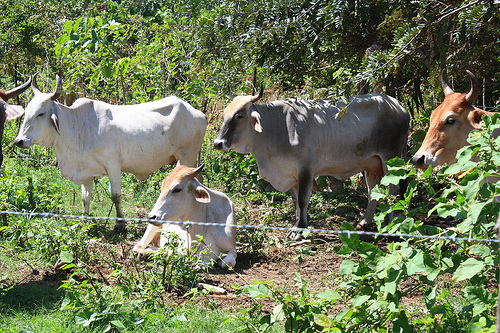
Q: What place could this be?
A: It is a field.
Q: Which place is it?
A: It is a field.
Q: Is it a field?
A: Yes, it is a field.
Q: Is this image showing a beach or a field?
A: It is showing a field.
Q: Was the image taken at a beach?
A: No, the picture was taken in a field.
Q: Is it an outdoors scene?
A: Yes, it is outdoors.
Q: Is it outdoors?
A: Yes, it is outdoors.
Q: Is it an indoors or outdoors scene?
A: It is outdoors.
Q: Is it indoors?
A: No, it is outdoors.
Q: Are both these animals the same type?
A: Yes, all the animals are bulls.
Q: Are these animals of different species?
A: No, all the animals are bulls.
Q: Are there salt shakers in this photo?
A: No, there are no salt shakers.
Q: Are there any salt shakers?
A: No, there are no salt shakers.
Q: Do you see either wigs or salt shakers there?
A: No, there are no salt shakers or wigs.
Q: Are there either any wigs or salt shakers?
A: No, there are no salt shakers or wigs.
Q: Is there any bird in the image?
A: No, there are no birds.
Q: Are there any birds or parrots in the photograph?
A: No, there are no birds or parrots.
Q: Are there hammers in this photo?
A: No, there are no hammers.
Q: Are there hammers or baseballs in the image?
A: No, there are no hammers or baseballs.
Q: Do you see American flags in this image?
A: No, there are no American flags.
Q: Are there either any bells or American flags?
A: No, there are no American flags or bells.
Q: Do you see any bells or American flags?
A: No, there are no American flags or bells.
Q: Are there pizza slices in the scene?
A: No, there are no pizza slices.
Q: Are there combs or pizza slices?
A: No, there are no pizza slices or combs.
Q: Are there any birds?
A: No, there are no birds.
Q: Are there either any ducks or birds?
A: No, there are no birds or ducks.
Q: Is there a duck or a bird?
A: No, there are no birds or ducks.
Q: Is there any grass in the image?
A: Yes, there is grass.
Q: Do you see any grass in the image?
A: Yes, there is grass.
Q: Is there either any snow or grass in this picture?
A: Yes, there is grass.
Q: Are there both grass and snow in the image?
A: No, there is grass but no snow.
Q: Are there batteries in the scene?
A: No, there are no batteries.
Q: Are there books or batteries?
A: No, there are no batteries or books.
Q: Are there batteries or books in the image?
A: No, there are no batteries or books.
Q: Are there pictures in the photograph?
A: No, there are no pictures.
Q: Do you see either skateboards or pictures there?
A: No, there are no pictures or skateboards.